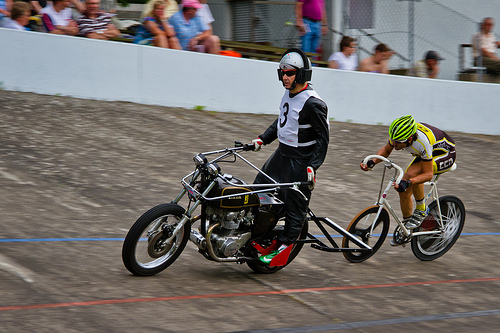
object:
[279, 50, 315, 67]
helmet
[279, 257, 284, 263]
stirrup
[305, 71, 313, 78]
headphones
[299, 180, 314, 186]
handlebar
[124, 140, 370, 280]
motorbike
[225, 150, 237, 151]
handlebar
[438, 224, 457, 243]
spokes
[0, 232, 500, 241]
line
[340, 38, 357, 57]
person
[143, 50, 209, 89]
stand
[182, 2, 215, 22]
person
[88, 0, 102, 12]
person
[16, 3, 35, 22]
person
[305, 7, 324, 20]
person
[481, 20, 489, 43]
person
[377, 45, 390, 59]
person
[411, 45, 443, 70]
person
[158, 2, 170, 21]
person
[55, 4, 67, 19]
person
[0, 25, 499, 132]
barrier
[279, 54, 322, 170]
rider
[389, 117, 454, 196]
rider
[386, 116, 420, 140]
helmet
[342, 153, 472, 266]
bike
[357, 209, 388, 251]
tire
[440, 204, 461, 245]
tire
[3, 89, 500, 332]
ground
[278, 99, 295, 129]
bib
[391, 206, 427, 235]
shoes